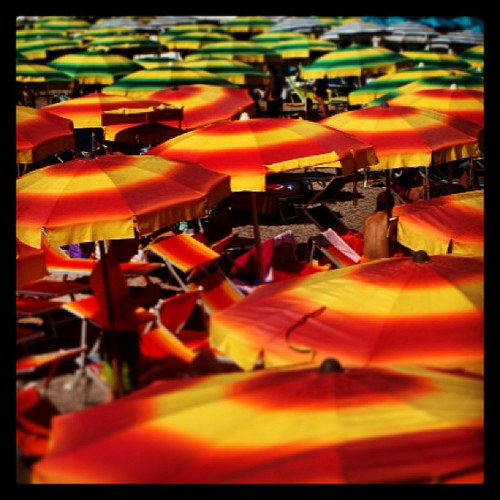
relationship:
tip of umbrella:
[237, 111, 250, 122] [146, 103, 378, 190]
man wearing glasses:
[90, 239, 160, 392] [119, 240, 139, 249]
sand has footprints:
[221, 82, 421, 262] [349, 212, 358, 222]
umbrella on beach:
[12, 13, 481, 485] [20, 21, 482, 486]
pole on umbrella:
[248, 191, 265, 283] [194, 94, 391, 311]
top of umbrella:
[246, 357, 424, 409] [12, 13, 481, 485]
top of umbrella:
[362, 99, 405, 116] [318, 101, 478, 164]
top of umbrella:
[214, 111, 266, 134] [12, 13, 481, 485]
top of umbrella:
[339, 41, 369, 54] [305, 43, 407, 76]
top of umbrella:
[70, 149, 116, 170] [12, 13, 481, 485]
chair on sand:
[316, 156, 356, 201] [212, 187, 387, 253]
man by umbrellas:
[359, 189, 400, 261] [15, 87, 481, 369]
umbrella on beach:
[308, 41, 408, 73] [20, 21, 482, 486]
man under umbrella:
[90, 239, 159, 390] [16, 154, 233, 402]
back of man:
[361, 212, 388, 259] [359, 189, 398, 261]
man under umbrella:
[359, 189, 398, 261] [12, 13, 481, 485]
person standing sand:
[260, 63, 287, 115] [326, 178, 385, 228]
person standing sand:
[264, 63, 286, 116] [326, 178, 385, 228]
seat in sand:
[303, 204, 396, 246] [231, 179, 407, 253]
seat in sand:
[150, 234, 221, 292] [41, 181, 408, 303]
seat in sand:
[15, 249, 87, 299] [41, 181, 408, 303]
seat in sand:
[147, 285, 209, 351] [41, 181, 408, 303]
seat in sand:
[63, 294, 108, 364] [41, 181, 408, 303]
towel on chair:
[265, 227, 298, 282] [265, 224, 318, 284]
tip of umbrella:
[316, 358, 343, 378] [12, 13, 481, 485]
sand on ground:
[221, 82, 421, 262] [14, 132, 497, 422]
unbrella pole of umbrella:
[92, 238, 120, 320] [16, 138, 226, 259]